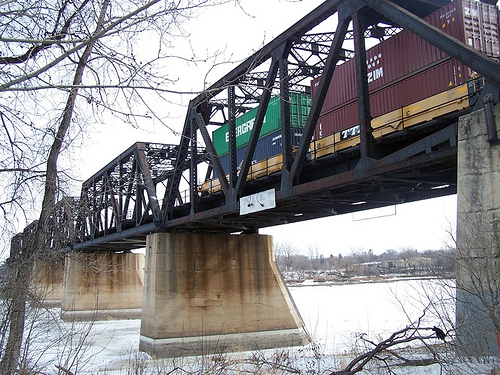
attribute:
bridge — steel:
[53, 23, 375, 207]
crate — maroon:
[303, 0, 499, 165]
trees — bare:
[3, 35, 200, 252]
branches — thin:
[14, 44, 144, 139]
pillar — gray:
[141, 227, 311, 360]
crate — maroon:
[305, 10, 497, 178]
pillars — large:
[458, 135, 496, 270]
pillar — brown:
[133, 234, 310, 344]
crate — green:
[212, 90, 310, 160]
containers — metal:
[311, 0, 499, 137]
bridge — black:
[172, 74, 333, 212]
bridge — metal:
[6, 3, 496, 365]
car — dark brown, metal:
[310, 21, 462, 142]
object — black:
[431, 322, 447, 340]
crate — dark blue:
[211, 124, 315, 191]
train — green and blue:
[202, 87, 319, 193]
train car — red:
[308, 6, 497, 126]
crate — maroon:
[309, 0, 499, 117]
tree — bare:
[1, 2, 221, 372]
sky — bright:
[1, 1, 388, 237]